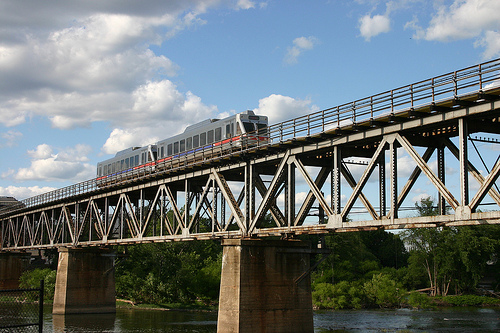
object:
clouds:
[1, 0, 500, 250]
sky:
[0, 0, 500, 252]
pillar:
[215, 236, 316, 333]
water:
[0, 301, 500, 333]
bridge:
[0, 56, 500, 333]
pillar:
[50, 248, 116, 316]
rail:
[0, 60, 499, 219]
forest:
[2, 197, 498, 310]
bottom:
[0, 211, 500, 253]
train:
[95, 109, 270, 194]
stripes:
[96, 134, 247, 181]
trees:
[156, 254, 183, 287]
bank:
[0, 304, 500, 333]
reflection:
[78, 327, 139, 332]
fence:
[0, 279, 46, 333]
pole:
[37, 280, 45, 331]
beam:
[389, 142, 399, 219]